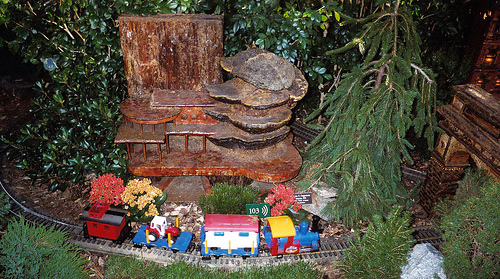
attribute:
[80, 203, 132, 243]
caboose — colored, red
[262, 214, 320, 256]
engine — blue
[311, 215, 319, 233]
smokestack — black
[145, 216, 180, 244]
tractor — colored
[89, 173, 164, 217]
flowers — colored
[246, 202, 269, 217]
sign — green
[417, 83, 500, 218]
tunnel — wooden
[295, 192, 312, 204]
sign — brown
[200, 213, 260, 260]
car — colored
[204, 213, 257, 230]
roof — red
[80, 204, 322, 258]
train — colored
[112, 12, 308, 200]
decoration — wooden, brown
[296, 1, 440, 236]
branch — bent, green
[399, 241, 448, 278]
rock — gray, white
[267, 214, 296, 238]
roof — yellow